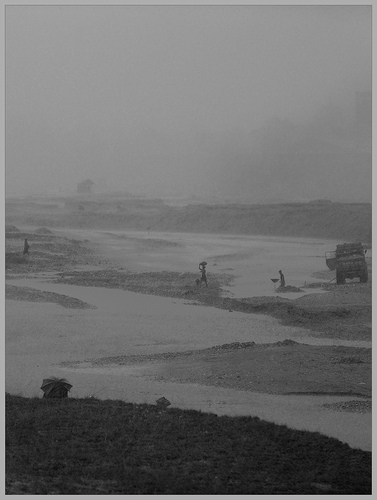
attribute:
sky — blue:
[11, 17, 287, 157]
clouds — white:
[11, 49, 79, 107]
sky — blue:
[150, 30, 270, 128]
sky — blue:
[145, 27, 359, 199]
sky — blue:
[12, 14, 362, 276]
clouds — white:
[274, 74, 351, 112]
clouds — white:
[237, 111, 293, 183]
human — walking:
[185, 254, 243, 283]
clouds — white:
[6, 6, 370, 198]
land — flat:
[62, 339, 371, 398]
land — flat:
[2, 228, 369, 340]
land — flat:
[6, 394, 370, 494]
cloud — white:
[158, 29, 223, 80]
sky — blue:
[6, 6, 375, 205]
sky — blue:
[85, 36, 286, 107]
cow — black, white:
[113, 401, 193, 444]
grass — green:
[36, 350, 326, 487]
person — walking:
[18, 237, 34, 260]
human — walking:
[196, 254, 213, 288]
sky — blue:
[15, 33, 361, 245]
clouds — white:
[160, 64, 235, 104]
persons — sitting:
[38, 364, 75, 415]